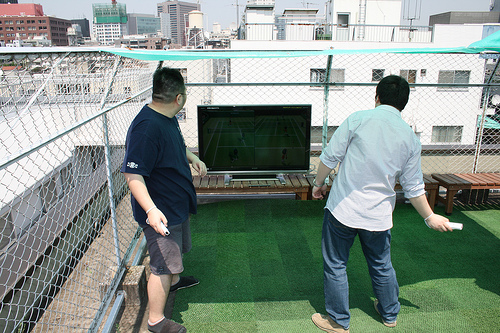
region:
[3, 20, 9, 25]
the window of a building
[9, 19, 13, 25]
the window of a building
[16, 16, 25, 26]
the window of a building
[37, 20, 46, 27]
the window of a building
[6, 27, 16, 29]
the window of a building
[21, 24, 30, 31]
the window of a building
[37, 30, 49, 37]
the window of a building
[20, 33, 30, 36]
the window of a building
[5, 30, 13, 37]
the window of a building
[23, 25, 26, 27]
the window of a building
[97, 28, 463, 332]
Two men are playing a game.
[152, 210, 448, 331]
People are standing on artificial grass.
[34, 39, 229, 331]
The man is standing next to a fence.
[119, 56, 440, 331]
Two men are playing a game on a television.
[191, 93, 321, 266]
The flat screen television is next to artificial grass.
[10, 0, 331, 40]
Several tall building are in the distance.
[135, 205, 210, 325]
The man is wearing shorts.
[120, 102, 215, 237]
The man is wearing a t-shirt.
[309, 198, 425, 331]
The man is wearing jeans.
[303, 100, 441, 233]
The man is wearing a white shirt.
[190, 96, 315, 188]
Screen of TV is on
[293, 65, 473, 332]
Person holds a white wii control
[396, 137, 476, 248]
Wii control on right hand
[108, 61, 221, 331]
Man has wii control on right hand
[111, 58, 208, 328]
Person wears black shirt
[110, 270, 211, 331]
Shoes are black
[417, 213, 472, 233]
Wii control is white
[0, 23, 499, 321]
People are on top of a roof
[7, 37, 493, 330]
Roof is fenced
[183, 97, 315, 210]
TV is on a wood table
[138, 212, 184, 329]
the leg of a person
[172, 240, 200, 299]
the leg of a person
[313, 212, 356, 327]
the leg of a person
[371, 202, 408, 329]
the leg of a person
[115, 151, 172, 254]
the hand of a person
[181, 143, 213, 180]
the hand of a person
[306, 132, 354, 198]
the hand of a person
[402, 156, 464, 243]
the hand of a person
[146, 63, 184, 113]
the head of a person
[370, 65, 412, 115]
the head of a person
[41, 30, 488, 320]
Two men playing a wii game outside.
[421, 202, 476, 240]
Wii control in right hand of man on right.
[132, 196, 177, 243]
Wii control in right hand of man on left.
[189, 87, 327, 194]
Large flat screen tv.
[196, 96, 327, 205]
Tv sitting on a wooden bench.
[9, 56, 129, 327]
Chain link fence.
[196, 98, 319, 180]
The tv is turned on.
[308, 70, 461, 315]
A man with dark hair on the right.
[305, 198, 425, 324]
A pair of blue jeans.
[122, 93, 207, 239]
Dark blue tee shirt.